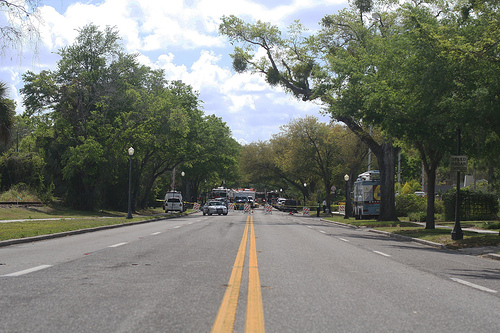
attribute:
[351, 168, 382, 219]
truck — blue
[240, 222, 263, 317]
lane divider — yellow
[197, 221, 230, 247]
street — blocked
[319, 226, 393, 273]
lines — white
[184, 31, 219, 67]
sky — cloudy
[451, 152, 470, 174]
sign — white, black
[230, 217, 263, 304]
double line — yellow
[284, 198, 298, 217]
car — parked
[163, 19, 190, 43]
clouds — white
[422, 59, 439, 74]
leaves — green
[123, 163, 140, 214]
pole — black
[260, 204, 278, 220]
barricade — red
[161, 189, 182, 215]
van — white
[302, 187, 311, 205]
lamp — tall, metal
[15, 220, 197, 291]
line — dashed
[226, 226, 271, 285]
lines — yellow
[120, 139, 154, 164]
lights — white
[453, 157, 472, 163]
lettters — black